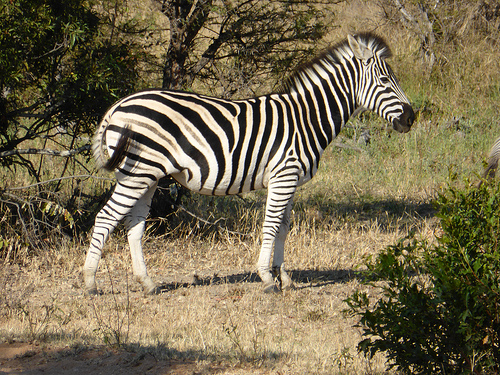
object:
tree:
[0, 0, 141, 214]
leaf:
[109, 91, 122, 101]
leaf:
[70, 33, 78, 51]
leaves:
[6, 24, 16, 33]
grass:
[317, 99, 499, 191]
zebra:
[77, 26, 422, 304]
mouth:
[394, 124, 411, 134]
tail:
[92, 116, 133, 171]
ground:
[4, 189, 445, 373]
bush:
[335, 166, 498, 373]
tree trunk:
[149, 1, 213, 216]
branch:
[179, 12, 253, 86]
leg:
[79, 172, 150, 297]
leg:
[127, 189, 162, 298]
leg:
[254, 177, 295, 297]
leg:
[271, 208, 294, 291]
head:
[342, 30, 417, 135]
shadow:
[153, 262, 427, 292]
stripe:
[106, 125, 180, 169]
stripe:
[113, 105, 210, 190]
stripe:
[105, 124, 190, 185]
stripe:
[123, 93, 227, 196]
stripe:
[161, 90, 235, 152]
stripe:
[270, 197, 291, 203]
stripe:
[271, 179, 297, 185]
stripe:
[264, 220, 282, 224]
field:
[2, 1, 498, 374]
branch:
[0, 142, 91, 158]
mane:
[277, 30, 394, 93]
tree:
[136, 0, 326, 196]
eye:
[379, 75, 390, 85]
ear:
[342, 30, 374, 60]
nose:
[400, 106, 419, 125]